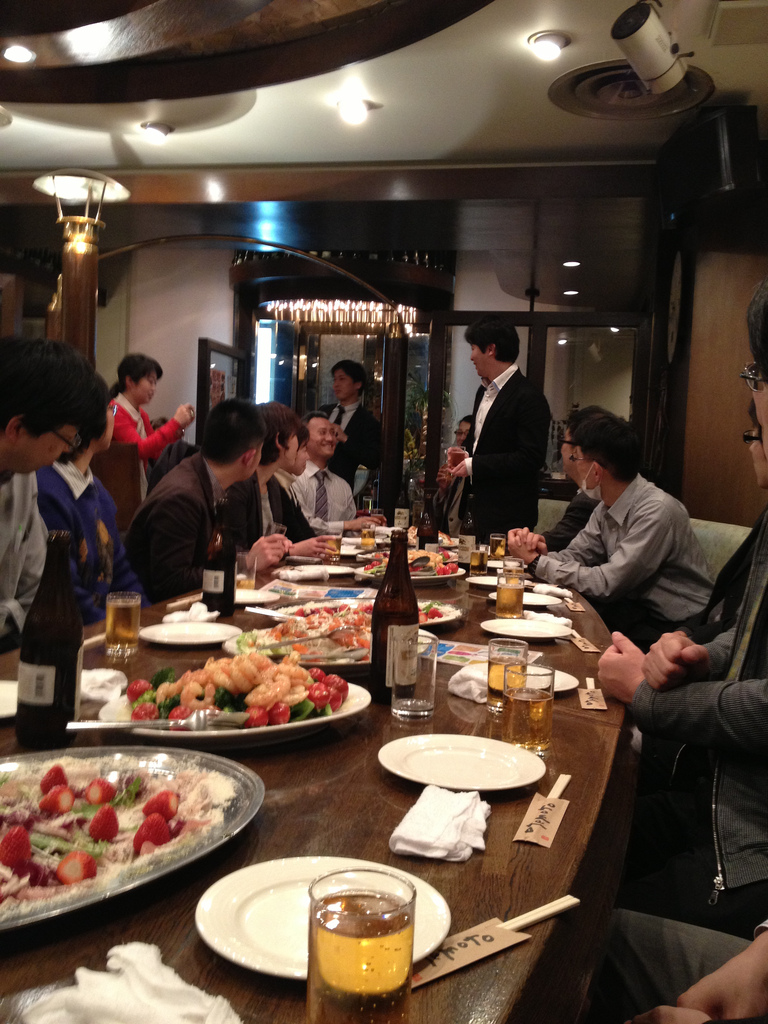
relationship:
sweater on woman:
[74, 393, 196, 473] [97, 347, 193, 541]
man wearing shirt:
[506, 418, 729, 659] [535, 484, 715, 626]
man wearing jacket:
[450, 307, 546, 526] [465, 374, 544, 535]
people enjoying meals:
[10, 307, 744, 1021] [3, 578, 462, 934]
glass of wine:
[390, 501, 413, 534] [373, 530, 423, 708]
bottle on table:
[367, 525, 420, 712] [10, 509, 652, 1020]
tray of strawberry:
[9, 735, 265, 950] [21, 776, 171, 861]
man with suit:
[457, 307, 560, 529] [461, 382, 567, 543]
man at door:
[295, 336, 375, 471] [234, 291, 437, 497]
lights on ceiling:
[335, 92, 388, 156] [65, 106, 612, 207]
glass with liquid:
[292, 853, 466, 1019] [315, 902, 458, 1020]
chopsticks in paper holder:
[470, 885, 637, 946] [414, 868, 641, 986]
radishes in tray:
[130, 786, 192, 840] [9, 736, 265, 950]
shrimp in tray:
[151, 650, 361, 736] [98, 614, 366, 742]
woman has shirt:
[97, 347, 193, 541] [30, 463, 204, 571]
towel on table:
[365, 786, 543, 865] [0, 512, 733, 1017]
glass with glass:
[303, 856, 417, 1019] [303, 856, 417, 1019]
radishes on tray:
[42, 800, 136, 900] [9, 736, 265, 950]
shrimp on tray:
[183, 656, 335, 704] [153, 656, 416, 781]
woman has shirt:
[97, 347, 193, 541] [27, 459, 183, 620]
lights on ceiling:
[312, 60, 395, 142] [69, 25, 659, 175]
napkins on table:
[386, 783, 492, 866] [10, 509, 652, 1020]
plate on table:
[389, 685, 620, 860] [10, 509, 652, 1020]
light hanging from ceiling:
[30, 167, 133, 252] [9, 19, 737, 213]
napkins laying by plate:
[386, 783, 492, 866] [375, 731, 546, 791]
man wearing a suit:
[450, 307, 546, 526] [464, 368, 549, 527]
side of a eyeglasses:
[51, 430, 76, 453] [51, 427, 84, 452]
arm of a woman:
[114, 397, 196, 458] [104, 346, 191, 461]